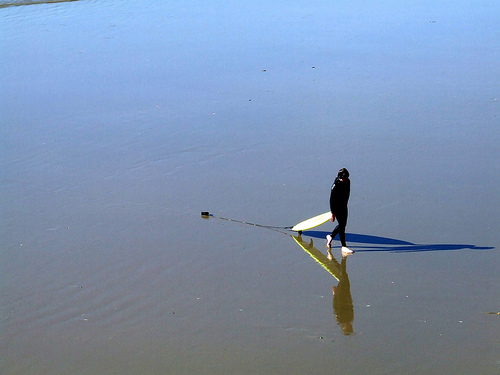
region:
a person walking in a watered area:
[164, 120, 417, 300]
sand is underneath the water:
[133, 250, 465, 374]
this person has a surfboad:
[190, 144, 424, 276]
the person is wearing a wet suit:
[318, 163, 360, 258]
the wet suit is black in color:
[323, 178, 363, 245]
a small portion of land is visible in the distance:
[1, 1, 86, 35]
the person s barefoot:
[326, 230, 352, 254]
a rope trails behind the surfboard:
[210, 204, 284, 245]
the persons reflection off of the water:
[294, 232, 371, 341]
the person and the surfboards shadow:
[308, 228, 493, 270]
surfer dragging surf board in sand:
[290, 154, 368, 268]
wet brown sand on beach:
[16, 33, 81, 102]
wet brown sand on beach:
[175, 36, 219, 86]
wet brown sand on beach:
[70, 124, 106, 150]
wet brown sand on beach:
[37, 192, 76, 238]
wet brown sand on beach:
[101, 310, 164, 348]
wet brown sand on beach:
[260, 310, 296, 335]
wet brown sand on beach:
[402, 305, 450, 335]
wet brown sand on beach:
[282, 28, 340, 89]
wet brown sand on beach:
[379, 59, 448, 125]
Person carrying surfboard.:
[290, 167, 360, 255]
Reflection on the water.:
[287, 231, 361, 338]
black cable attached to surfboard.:
[193, 205, 295, 237]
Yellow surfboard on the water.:
[292, 210, 332, 235]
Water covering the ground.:
[0, 3, 495, 373]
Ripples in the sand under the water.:
[7, 238, 182, 345]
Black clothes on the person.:
[325, 168, 356, 255]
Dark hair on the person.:
[331, 168, 352, 185]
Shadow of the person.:
[348, 240, 498, 257]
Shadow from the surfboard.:
[304, 225, 412, 247]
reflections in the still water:
[278, 238, 359, 339]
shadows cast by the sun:
[310, 227, 495, 257]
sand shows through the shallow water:
[0, 255, 496, 370]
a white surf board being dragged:
[290, 205, 335, 230]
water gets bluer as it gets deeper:
[0, 0, 495, 130]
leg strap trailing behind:
[195, 206, 290, 227]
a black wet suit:
[325, 172, 350, 242]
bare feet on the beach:
[325, 230, 355, 255]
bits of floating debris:
[231, 60, 331, 105]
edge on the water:
[1, 0, 73, 18]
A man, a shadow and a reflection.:
[287, 165, 490, 335]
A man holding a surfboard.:
[290, 156, 491, 252]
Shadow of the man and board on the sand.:
[286, 227, 497, 252]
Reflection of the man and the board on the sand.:
[288, 230, 356, 340]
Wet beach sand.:
[0, 0, 496, 373]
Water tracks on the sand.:
[0, 245, 295, 369]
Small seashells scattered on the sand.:
[16, 265, 491, 372]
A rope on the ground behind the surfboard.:
[197, 210, 292, 230]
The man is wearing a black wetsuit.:
[327, 177, 353, 244]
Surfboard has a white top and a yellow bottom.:
[290, 207, 345, 280]